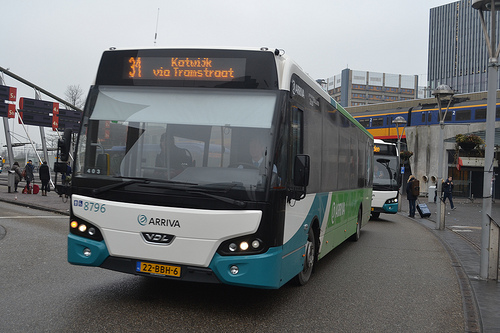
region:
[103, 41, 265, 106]
directional read on front of city bus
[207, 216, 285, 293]
headlights on front of city bus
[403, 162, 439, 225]
woman pulling rolling suitcase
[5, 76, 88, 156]
directional sings with red arrows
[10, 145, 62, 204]
people walking with luggage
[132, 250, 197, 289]
yellow license plate on front of bus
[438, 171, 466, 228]
person walking in to bus terminal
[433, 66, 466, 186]
street light on letal pole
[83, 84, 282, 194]
windshield of large city bus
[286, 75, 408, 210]
passenger windows on city bus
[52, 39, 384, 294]
a blue and white bus parked at a terminal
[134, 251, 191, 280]
a yellow license plate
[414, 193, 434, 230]
a suitcase pulled by a person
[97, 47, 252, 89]
a destination sign on a bus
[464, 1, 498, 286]
a light pole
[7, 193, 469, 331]
a gray paved drive at a bus terminal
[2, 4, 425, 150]
a pale grey sky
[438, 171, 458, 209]
a person walking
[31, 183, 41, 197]
a red suitcase held by a person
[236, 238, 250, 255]
a headlight on the front of a bus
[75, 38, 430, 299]
bus with white green and blue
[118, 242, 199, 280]
yellow license plate with black lettering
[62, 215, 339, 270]
headlights on bus turned on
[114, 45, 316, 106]
orange neon lettering on sign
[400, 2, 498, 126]
tall building in background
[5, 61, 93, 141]
blue and red signs on metal pole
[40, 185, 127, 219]
teal numbers on white bus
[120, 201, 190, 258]
black letters on white bus front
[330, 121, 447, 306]
second bus parked at curb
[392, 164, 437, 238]
person with rolling suitcase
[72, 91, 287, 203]
the windshield of a bus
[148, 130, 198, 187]
a person inside a bus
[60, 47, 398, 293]
a blue, white, and green bus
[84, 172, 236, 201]
two windshield wipers on a bus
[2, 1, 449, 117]
a gloomy gray sky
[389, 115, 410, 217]
a light pole by a bus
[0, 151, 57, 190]
a line of people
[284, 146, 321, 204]
a sideview mirror on a bus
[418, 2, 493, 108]
a concrete building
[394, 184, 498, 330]
a walkway next to a roadway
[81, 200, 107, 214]
THE NUMBER 8796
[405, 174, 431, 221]
MAN HOLDING A SUITCASE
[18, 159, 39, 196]
MAN HOLDING A RED SUITCASE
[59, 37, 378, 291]
BLUE WHITE AND GREEN PASSENGER BUS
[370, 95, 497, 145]
BLUE PASSENGER TRAIN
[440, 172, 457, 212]
MAN WALKING ON THE SIDEWALK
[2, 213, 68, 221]
WHITE LINE IN THE STREET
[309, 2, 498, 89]
TWO BUILDINGS IN THE BACKGROUND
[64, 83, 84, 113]
TREE WITH NO LEAVES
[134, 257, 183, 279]
YELLOW LICENSE PLATE